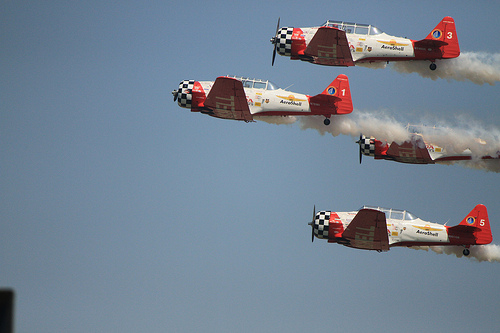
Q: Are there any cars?
A: No, there are no cars.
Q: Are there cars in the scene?
A: No, there are no cars.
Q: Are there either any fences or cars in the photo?
A: No, there are no cars or fences.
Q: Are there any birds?
A: No, there are no birds.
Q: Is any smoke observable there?
A: Yes, there is smoke.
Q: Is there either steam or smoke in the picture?
A: Yes, there is smoke.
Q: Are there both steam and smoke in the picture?
A: No, there is smoke but no steam.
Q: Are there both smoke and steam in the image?
A: No, there is smoke but no steam.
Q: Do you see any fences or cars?
A: No, there are no cars or fences.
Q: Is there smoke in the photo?
A: Yes, there is smoke.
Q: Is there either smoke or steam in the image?
A: Yes, there is smoke.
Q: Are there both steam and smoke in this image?
A: No, there is smoke but no steam.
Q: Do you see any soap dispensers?
A: No, there are no soap dispensers.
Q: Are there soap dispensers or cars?
A: No, there are no soap dispensers or cars.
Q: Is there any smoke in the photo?
A: Yes, there is smoke.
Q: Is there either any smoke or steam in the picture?
A: Yes, there is smoke.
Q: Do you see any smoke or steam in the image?
A: Yes, there is smoke.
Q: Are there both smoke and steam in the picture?
A: No, there is smoke but no steam.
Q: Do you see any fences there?
A: No, there are no fences.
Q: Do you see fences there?
A: No, there are no fences.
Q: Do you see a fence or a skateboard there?
A: No, there are no fences or skateboards.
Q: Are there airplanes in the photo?
A: Yes, there is an airplane.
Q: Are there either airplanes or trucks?
A: Yes, there is an airplane.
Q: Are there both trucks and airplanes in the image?
A: No, there is an airplane but no trucks.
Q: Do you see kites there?
A: No, there are no kites.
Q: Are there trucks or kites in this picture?
A: No, there are no kites or trucks.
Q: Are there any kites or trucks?
A: No, there are no kites or trucks.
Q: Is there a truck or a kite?
A: No, there are no kites or trucks.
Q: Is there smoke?
A: Yes, there is smoke.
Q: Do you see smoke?
A: Yes, there is smoke.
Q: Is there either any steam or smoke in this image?
A: Yes, there is smoke.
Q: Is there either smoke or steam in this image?
A: Yes, there is smoke.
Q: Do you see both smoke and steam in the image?
A: No, there is smoke but no steam.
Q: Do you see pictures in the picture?
A: No, there are no pictures.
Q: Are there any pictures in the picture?
A: No, there are no pictures.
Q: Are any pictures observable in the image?
A: No, there are no pictures.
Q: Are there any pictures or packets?
A: No, there are no pictures or packets.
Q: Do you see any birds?
A: No, there are no birds.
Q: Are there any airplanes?
A: Yes, there is an airplane.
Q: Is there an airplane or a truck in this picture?
A: Yes, there is an airplane.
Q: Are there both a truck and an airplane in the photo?
A: No, there is an airplane but no trucks.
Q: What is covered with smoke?
A: The airplane is covered with smoke.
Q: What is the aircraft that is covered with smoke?
A: The aircraft is an airplane.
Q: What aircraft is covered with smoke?
A: The aircraft is an airplane.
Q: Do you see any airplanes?
A: Yes, there is an airplane.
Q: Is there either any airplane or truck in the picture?
A: Yes, there is an airplane.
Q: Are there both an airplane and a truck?
A: No, there is an airplane but no trucks.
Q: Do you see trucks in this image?
A: No, there are no trucks.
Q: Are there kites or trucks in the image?
A: No, there are no trucks or kites.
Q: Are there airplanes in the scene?
A: Yes, there is an airplane.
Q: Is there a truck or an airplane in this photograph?
A: Yes, there is an airplane.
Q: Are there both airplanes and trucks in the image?
A: No, there is an airplane but no trucks.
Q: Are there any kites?
A: No, there are no kites.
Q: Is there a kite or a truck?
A: No, there are no kites or trucks.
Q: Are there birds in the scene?
A: No, there are no birds.